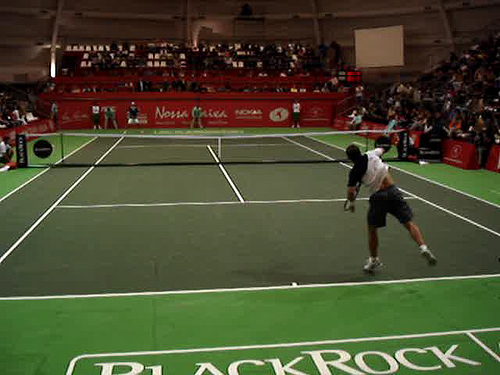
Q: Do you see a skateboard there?
A: No, there are no skateboards.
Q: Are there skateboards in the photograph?
A: No, there are no skateboards.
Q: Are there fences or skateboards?
A: No, there are no skateboards or fences.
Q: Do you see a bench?
A: No, there are no benches.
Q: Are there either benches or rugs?
A: No, there are no benches or rugs.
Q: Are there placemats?
A: No, there are no placemats.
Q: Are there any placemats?
A: No, there are no placemats.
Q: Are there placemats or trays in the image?
A: No, there are no placemats or trays.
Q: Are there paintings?
A: No, there are no paintings.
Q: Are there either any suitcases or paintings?
A: No, there are no paintings or suitcases.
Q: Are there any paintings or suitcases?
A: No, there are no paintings or suitcases.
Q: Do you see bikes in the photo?
A: No, there are no bikes.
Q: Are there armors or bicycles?
A: No, there are no bicycles or armors.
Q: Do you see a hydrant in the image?
A: No, there are no fire hydrants.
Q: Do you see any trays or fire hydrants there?
A: No, there are no fire hydrants or trays.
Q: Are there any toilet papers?
A: No, there are no toilet papers.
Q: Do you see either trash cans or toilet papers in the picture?
A: No, there are no toilet papers or trash cans.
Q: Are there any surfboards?
A: No, there are no surfboards.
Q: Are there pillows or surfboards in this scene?
A: No, there are no surfboards or pillows.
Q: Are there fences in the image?
A: No, there are no fences.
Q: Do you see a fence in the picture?
A: No, there are no fences.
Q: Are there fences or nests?
A: No, there are no fences or nests.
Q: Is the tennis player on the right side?
A: Yes, the player is on the right of the image.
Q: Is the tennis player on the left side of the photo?
A: No, the player is on the right of the image.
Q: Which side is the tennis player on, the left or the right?
A: The player is on the right of the image.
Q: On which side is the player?
A: The player is on the right of the image.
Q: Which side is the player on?
A: The player is on the right of the image.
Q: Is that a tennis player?
A: Yes, that is a tennis player.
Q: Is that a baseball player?
A: No, that is a tennis player.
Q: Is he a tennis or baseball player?
A: That is a tennis player.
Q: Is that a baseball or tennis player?
A: That is a tennis player.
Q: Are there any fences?
A: No, there are no fences.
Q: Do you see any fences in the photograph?
A: No, there are no fences.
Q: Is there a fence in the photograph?
A: No, there are no fences.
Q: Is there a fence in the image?
A: No, there are no fences.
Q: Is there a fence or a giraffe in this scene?
A: No, there are no fences or giraffes.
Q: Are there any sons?
A: No, there are no sons.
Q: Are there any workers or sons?
A: No, there are no sons or workers.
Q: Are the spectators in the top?
A: Yes, the spectators are in the top of the image.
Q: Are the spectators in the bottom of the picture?
A: No, the spectators are in the top of the image.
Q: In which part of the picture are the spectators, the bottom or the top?
A: The spectators are in the top of the image.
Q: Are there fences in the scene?
A: No, there are no fences.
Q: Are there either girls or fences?
A: No, there are no fences or girls.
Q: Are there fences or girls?
A: No, there are no fences or girls.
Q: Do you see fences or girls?
A: No, there are no fences or girls.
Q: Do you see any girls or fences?
A: No, there are no fences or girls.